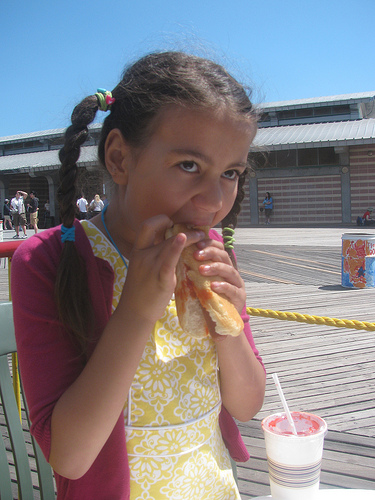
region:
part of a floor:
[320, 330, 328, 342]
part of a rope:
[291, 310, 297, 336]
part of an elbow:
[88, 413, 93, 426]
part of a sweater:
[44, 330, 72, 354]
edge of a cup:
[277, 433, 283, 454]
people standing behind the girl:
[4, 190, 99, 224]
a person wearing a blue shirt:
[256, 191, 275, 224]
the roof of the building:
[268, 115, 363, 142]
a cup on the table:
[263, 407, 319, 498]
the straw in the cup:
[272, 376, 298, 434]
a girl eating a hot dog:
[22, 49, 283, 452]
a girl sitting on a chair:
[4, 82, 254, 496]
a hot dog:
[172, 224, 239, 339]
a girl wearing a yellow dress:
[23, 91, 253, 491]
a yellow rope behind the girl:
[242, 305, 362, 328]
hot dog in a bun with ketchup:
[163, 220, 242, 345]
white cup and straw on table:
[261, 365, 329, 497]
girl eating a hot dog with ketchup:
[6, 43, 273, 498]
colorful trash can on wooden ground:
[337, 226, 373, 292]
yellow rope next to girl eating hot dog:
[240, 301, 374, 336]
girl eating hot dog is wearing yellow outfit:
[8, 42, 273, 497]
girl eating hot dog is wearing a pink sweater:
[8, 43, 269, 496]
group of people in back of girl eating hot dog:
[1, 185, 109, 243]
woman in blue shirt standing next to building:
[256, 185, 279, 230]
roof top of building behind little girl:
[0, 87, 373, 178]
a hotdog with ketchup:
[163, 220, 243, 346]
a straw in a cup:
[266, 362, 328, 491]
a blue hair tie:
[53, 216, 79, 244]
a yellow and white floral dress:
[77, 224, 247, 499]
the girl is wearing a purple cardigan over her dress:
[0, 221, 252, 495]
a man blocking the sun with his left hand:
[8, 187, 30, 239]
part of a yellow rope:
[241, 302, 371, 336]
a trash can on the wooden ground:
[336, 229, 374, 293]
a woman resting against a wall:
[257, 186, 277, 228]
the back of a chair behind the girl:
[1, 297, 52, 496]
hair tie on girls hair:
[92, 84, 113, 115]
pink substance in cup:
[298, 411, 318, 435]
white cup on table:
[267, 408, 332, 498]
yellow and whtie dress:
[131, 347, 201, 480]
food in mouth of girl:
[181, 203, 218, 260]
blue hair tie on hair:
[53, 221, 76, 254]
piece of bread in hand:
[183, 297, 248, 339]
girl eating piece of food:
[105, 56, 290, 341]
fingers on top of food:
[189, 246, 232, 308]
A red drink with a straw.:
[259, 366, 334, 491]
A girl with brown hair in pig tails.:
[16, 45, 272, 293]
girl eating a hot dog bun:
[175, 224, 202, 265]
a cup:
[264, 409, 326, 495]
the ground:
[299, 345, 337, 389]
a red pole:
[2, 240, 15, 252]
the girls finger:
[165, 232, 183, 280]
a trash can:
[339, 229, 372, 287]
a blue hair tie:
[58, 224, 75, 242]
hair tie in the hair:
[60, 223, 76, 247]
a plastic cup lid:
[264, 410, 339, 445]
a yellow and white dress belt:
[122, 416, 217, 455]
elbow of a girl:
[46, 448, 84, 484]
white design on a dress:
[176, 376, 219, 418]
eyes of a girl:
[181, 156, 235, 189]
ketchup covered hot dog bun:
[163, 227, 240, 345]